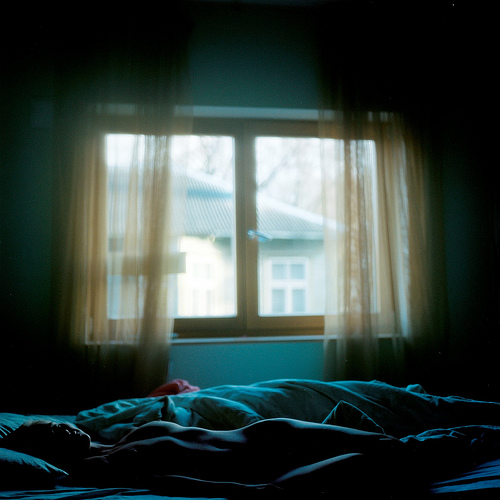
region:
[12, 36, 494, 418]
a window with curtains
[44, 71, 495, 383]
a window with sheer curtains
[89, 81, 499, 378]
a curtain on a window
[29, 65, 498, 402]
sheer curtains on a window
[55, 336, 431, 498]
a person alying in the bed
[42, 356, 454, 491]
a person laying inside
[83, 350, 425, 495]
a person laying down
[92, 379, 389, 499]
a person laying down in the bed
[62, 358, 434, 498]
a person laying down inside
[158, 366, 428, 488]
a bed with a person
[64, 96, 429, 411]
curtains on the window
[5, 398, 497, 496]
person laying on the bed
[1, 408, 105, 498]
head on the pillow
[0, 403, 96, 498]
pillow on the head of the bed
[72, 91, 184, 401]
sheer curtain on the window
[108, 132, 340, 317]
house visible through the window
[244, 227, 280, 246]
silver handle on the window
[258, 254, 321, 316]
window on the side of the house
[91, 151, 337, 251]
the roof is sloped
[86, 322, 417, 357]
ledge under the window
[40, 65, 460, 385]
curtains are color brown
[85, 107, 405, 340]
window is color brown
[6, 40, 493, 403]
room has a window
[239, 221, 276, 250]
handle in the window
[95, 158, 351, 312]
a house can be seen through a window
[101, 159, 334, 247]
roof of house is black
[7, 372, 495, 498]
woman lying on a bed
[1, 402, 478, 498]
a woman is naked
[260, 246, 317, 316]
a window color white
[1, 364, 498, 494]
comforter next a woman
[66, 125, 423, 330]
a beautiful window in wall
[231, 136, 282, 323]
a gap in the wall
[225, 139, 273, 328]
a plastic divider in window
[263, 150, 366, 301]
a glass in the window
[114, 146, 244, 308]
a glass in the another window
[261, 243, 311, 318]
a display of another windows of home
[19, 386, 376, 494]
a girl sleeping in bed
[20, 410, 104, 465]
face of the girl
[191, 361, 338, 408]
a bed sheet in the bed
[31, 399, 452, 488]
a girl sleeping deeply in bed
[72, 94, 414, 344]
this is a window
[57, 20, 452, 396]
this is a window and curtain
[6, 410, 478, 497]
a woman lying in bed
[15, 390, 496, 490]
the woman is nude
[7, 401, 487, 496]
she is nude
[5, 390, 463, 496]
she is bare naked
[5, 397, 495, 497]
a nude woman in a bed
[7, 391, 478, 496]
a nude woman lying in bed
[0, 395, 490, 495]
a naked woman in bed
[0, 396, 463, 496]
a naked woman lying on a bed